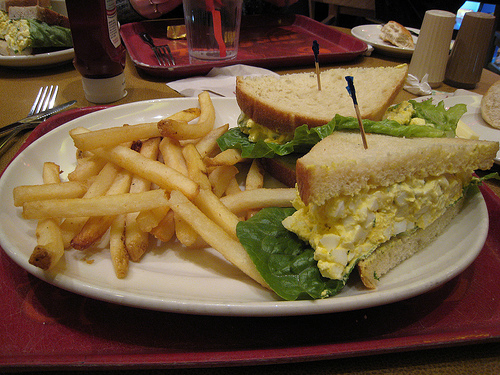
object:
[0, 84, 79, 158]
fork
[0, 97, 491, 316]
dish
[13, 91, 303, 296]
french fries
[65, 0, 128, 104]
bottle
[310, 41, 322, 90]
toothpick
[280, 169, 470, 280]
egg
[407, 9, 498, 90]
bottles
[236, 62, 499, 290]
egg sandwich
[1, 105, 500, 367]
tray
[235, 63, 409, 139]
bread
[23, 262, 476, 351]
shadow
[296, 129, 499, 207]
bread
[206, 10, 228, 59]
straw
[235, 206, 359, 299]
leaf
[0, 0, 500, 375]
table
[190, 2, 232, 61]
glass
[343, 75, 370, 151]
tooth pick